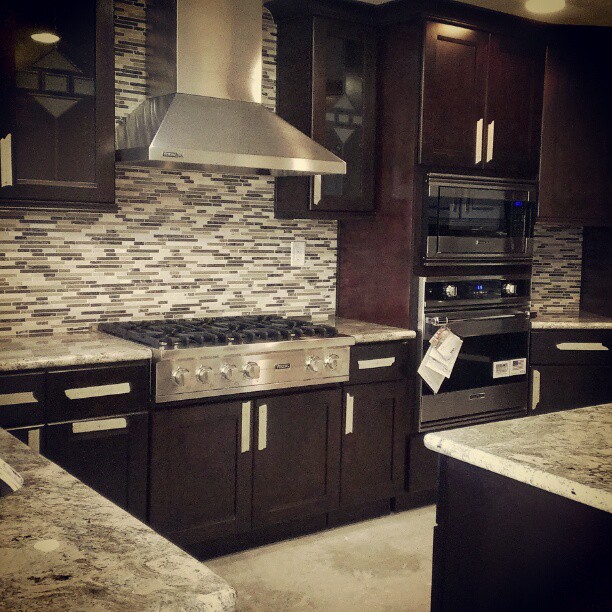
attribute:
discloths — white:
[407, 321, 462, 398]